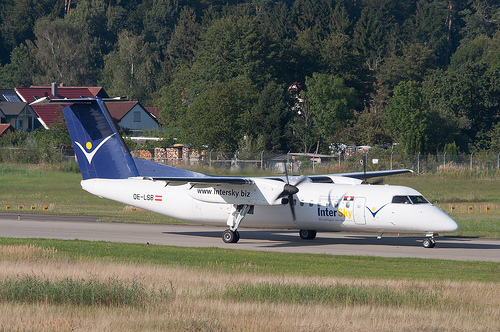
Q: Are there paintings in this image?
A: No, there are no paintings.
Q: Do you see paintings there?
A: No, there are no paintings.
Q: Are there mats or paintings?
A: No, there are no paintings or mats.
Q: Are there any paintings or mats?
A: No, there are no paintings or mats.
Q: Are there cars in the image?
A: No, there are no cars.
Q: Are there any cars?
A: No, there are no cars.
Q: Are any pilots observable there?
A: No, there are no pilots.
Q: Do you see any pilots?
A: No, there are no pilots.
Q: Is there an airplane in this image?
A: Yes, there is an airplane.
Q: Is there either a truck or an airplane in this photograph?
A: Yes, there is an airplane.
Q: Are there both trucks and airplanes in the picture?
A: No, there is an airplane but no trucks.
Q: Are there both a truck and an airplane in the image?
A: No, there is an airplane but no trucks.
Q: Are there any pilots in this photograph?
A: No, there are no pilots.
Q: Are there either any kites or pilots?
A: No, there are no pilots or kites.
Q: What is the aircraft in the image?
A: The aircraft is an airplane.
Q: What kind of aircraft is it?
A: The aircraft is an airplane.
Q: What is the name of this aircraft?
A: That is an airplane.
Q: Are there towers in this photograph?
A: No, there are no towers.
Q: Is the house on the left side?
A: Yes, the house is on the left of the image.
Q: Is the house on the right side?
A: No, the house is on the left of the image.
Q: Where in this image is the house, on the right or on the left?
A: The house is on the left of the image.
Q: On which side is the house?
A: The house is on the left of the image.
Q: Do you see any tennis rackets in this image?
A: No, there are no tennis rackets.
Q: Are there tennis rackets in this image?
A: No, there are no tennis rackets.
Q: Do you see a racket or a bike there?
A: No, there are no rackets or bikes.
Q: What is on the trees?
A: The leaves are on the trees.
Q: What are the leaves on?
A: The leaves are on the trees.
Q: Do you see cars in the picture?
A: No, there are no cars.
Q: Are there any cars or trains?
A: No, there are no cars or trains.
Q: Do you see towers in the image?
A: No, there are no towers.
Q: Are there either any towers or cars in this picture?
A: No, there are no towers or cars.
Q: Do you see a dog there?
A: No, there are no dogs.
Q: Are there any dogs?
A: No, there are no dogs.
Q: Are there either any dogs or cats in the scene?
A: No, there are no dogs or cats.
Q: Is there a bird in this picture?
A: No, there are no birds.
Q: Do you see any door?
A: Yes, there is a door.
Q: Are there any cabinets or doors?
A: Yes, there is a door.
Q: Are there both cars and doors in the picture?
A: No, there is a door but no cars.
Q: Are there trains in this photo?
A: No, there are no trains.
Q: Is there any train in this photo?
A: No, there are no trains.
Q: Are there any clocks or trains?
A: No, there are no trains or clocks.